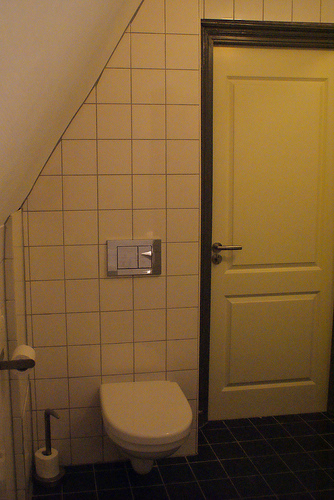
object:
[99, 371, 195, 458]
closed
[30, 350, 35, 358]
white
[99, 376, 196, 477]
porcelain toilet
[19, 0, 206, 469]
wall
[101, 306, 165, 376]
four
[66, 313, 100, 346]
tiles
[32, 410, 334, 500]
floor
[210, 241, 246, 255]
long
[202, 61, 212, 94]
dark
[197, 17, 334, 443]
frame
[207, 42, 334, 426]
door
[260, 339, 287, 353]
tint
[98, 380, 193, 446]
toilet lit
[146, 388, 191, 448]
down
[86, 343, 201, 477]
modern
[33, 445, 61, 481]
toilet paper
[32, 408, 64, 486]
holder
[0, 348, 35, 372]
holder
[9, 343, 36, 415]
toilet paper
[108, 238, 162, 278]
silver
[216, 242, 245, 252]
door handle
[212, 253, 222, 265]
lock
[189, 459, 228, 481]
tile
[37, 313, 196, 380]
cream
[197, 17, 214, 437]
trim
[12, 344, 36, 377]
roll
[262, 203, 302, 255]
yellowish